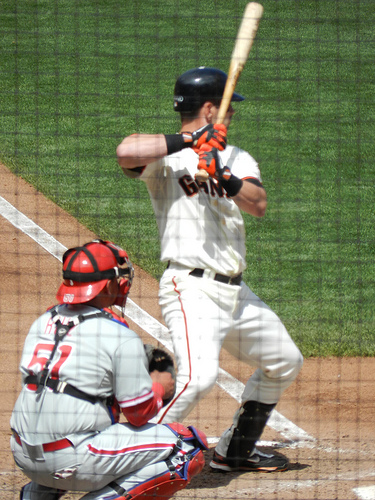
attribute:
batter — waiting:
[116, 70, 307, 477]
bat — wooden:
[196, 1, 266, 186]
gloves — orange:
[189, 119, 229, 181]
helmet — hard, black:
[173, 66, 248, 114]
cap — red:
[50, 238, 138, 308]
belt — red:
[5, 434, 76, 457]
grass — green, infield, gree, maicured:
[3, 1, 374, 367]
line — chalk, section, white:
[0, 195, 318, 444]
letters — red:
[25, 314, 72, 398]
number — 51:
[22, 342, 73, 395]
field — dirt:
[0, 3, 373, 495]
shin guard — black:
[227, 397, 278, 466]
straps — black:
[24, 306, 106, 409]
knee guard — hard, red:
[177, 418, 213, 480]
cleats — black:
[206, 446, 294, 477]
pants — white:
[149, 263, 307, 460]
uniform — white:
[137, 140, 305, 452]